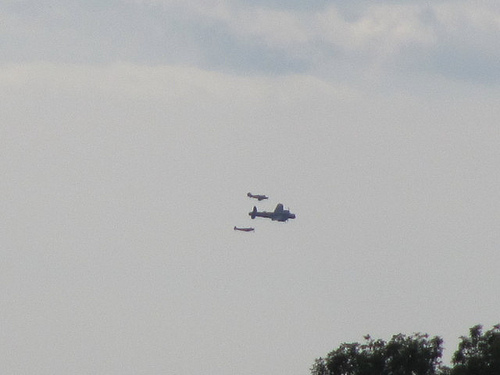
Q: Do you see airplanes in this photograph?
A: Yes, there are airplanes.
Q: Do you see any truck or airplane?
A: Yes, there are airplanes.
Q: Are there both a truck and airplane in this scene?
A: No, there are airplanes but no trucks.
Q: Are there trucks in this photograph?
A: No, there are no trucks.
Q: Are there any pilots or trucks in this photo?
A: No, there are no trucks or pilots.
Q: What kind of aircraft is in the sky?
A: The aircraft is airplanes.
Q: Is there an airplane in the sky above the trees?
A: Yes, there are airplanes in the sky.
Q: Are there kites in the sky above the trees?
A: No, there are airplanes in the sky.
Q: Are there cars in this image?
A: No, there are no cars.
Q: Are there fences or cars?
A: No, there are no cars or fences.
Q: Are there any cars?
A: No, there are no cars.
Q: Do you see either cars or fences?
A: No, there are no cars or fences.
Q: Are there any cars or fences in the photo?
A: No, there are no cars or fences.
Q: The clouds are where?
A: The clouds are in the sky.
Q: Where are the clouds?
A: The clouds are in the sky.